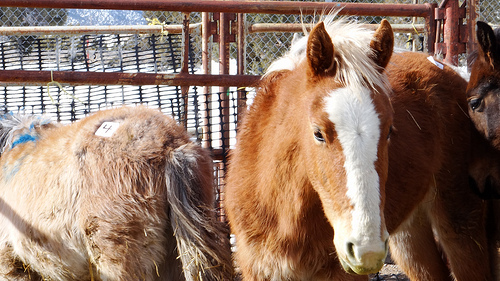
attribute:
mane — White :
[265, 0, 387, 92]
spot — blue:
[7, 131, 37, 149]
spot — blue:
[28, 116, 52, 128]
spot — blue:
[6, 154, 27, 176]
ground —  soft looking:
[423, 128, 453, 174]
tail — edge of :
[129, 138, 274, 275]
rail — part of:
[173, 34, 203, 116]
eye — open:
[311, 127, 328, 143]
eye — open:
[388, 122, 394, 139]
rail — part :
[1, 60, 264, 280]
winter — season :
[75, 24, 405, 270]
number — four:
[89, 117, 126, 142]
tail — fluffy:
[162, 138, 219, 277]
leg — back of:
[82, 171, 174, 278]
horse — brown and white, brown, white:
[226, 17, 498, 278]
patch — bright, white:
[323, 85, 385, 256]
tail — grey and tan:
[141, 135, 218, 268]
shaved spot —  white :
[97, 116, 118, 137]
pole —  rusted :
[5, 53, 495, 104]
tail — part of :
[165, 130, 228, 277]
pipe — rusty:
[118, 17, 185, 43]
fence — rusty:
[1, 1, 476, 277]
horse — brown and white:
[208, 49, 449, 276]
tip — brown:
[350, 242, 416, 278]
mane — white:
[303, 8, 399, 94]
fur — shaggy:
[17, 124, 210, 259]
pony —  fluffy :
[6, 89, 223, 267]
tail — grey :
[147, 114, 223, 279]